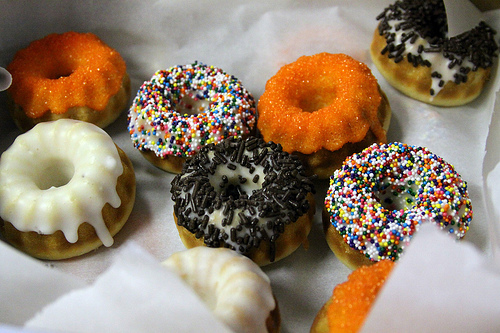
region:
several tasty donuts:
[1, 4, 483, 329]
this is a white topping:
[0, 125, 129, 252]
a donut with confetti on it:
[326, 144, 467, 252]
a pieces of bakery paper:
[123, 3, 320, 49]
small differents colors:
[334, 217, 389, 242]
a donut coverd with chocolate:
[173, 142, 305, 244]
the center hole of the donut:
[297, 84, 334, 113]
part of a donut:
[312, 262, 395, 330]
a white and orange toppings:
[8, 34, 122, 236]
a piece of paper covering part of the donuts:
[354, 224, 483, 328]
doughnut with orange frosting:
[15, 31, 130, 125]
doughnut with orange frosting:
[260, 58, 400, 165]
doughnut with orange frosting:
[309, 263, 403, 328]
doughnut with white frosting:
[8, 120, 136, 249]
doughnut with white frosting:
[163, 247, 280, 331]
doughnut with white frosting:
[176, 144, 313, 258]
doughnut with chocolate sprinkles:
[178, 135, 315, 255]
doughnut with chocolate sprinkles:
[367, 0, 488, 102]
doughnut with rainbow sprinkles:
[135, 60, 262, 157]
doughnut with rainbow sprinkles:
[336, 148, 475, 255]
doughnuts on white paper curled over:
[10, 6, 485, 321]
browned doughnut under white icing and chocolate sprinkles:
[375, 5, 490, 100]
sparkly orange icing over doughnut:
[257, 50, 387, 150]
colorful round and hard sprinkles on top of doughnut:
[325, 142, 470, 257]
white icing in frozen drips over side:
[1, 121, 121, 247]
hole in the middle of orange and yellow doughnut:
[10, 30, 125, 120]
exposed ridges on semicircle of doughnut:
[165, 245, 280, 326]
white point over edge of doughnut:
[416, 55, 456, 105]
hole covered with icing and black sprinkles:
[170, 145, 310, 250]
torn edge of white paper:
[477, 101, 497, 262]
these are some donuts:
[28, 48, 440, 289]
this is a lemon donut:
[54, 113, 151, 241]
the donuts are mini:
[82, 149, 312, 304]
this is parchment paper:
[382, 282, 411, 323]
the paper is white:
[403, 270, 448, 323]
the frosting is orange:
[262, 90, 297, 145]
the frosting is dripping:
[72, 168, 128, 230]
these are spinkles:
[213, 170, 259, 227]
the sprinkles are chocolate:
[230, 187, 267, 249]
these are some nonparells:
[298, 199, 413, 234]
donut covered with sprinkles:
[123, 57, 254, 168]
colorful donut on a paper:
[127, 57, 257, 168]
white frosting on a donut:
[0, 115, 140, 260]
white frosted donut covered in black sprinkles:
[170, 135, 320, 256]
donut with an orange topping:
[255, 50, 395, 168]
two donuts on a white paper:
[0, 27, 137, 262]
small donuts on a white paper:
[0, 2, 497, 330]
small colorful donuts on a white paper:
[0, 0, 495, 330]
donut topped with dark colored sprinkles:
[165, 135, 320, 265]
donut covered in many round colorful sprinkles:
[320, 140, 475, 265]